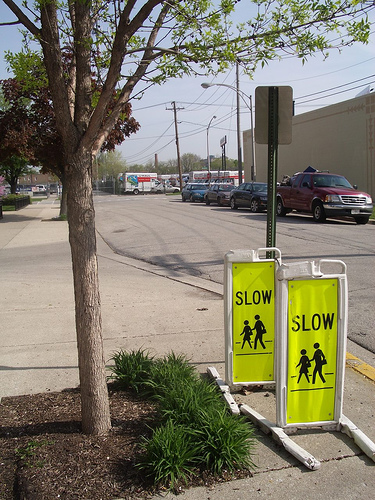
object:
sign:
[228, 257, 279, 387]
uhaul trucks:
[109, 160, 247, 199]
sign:
[223, 243, 348, 429]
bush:
[102, 344, 156, 396]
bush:
[159, 383, 232, 421]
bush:
[187, 407, 258, 470]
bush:
[136, 421, 206, 488]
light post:
[201, 78, 259, 185]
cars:
[273, 169, 373, 225]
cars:
[201, 182, 238, 206]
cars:
[179, 180, 211, 204]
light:
[200, 81, 210, 90]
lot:
[93, 162, 248, 196]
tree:
[0, 0, 373, 435]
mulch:
[1, 374, 207, 498]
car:
[228, 177, 270, 214]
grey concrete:
[118, 270, 177, 329]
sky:
[158, 63, 228, 127]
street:
[91, 162, 374, 442]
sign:
[286, 278, 338, 424]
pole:
[165, 100, 185, 200]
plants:
[143, 0, 275, 83]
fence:
[94, 173, 186, 198]